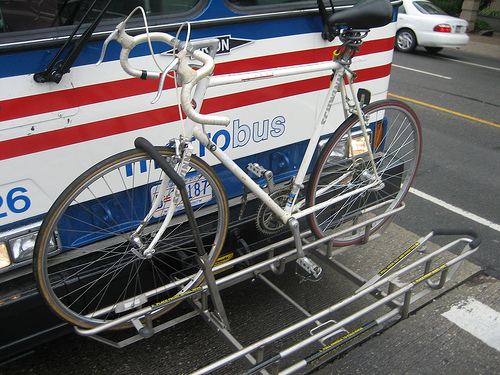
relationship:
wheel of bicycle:
[53, 131, 217, 310] [39, 54, 415, 290]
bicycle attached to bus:
[39, 54, 415, 290] [3, 2, 413, 280]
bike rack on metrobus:
[118, 234, 469, 374] [3, 2, 413, 280]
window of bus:
[6, 4, 187, 24] [3, 2, 413, 280]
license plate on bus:
[131, 176, 205, 207] [2, 43, 396, 194]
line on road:
[393, 60, 463, 89] [435, 130, 492, 181]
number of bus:
[1, 185, 40, 215] [3, 2, 413, 280]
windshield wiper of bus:
[37, 12, 106, 88] [3, 2, 413, 280]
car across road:
[396, 1, 479, 59] [435, 130, 492, 181]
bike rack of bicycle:
[118, 234, 469, 374] [39, 54, 415, 290]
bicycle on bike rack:
[39, 54, 415, 290] [118, 234, 469, 374]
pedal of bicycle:
[294, 252, 331, 279] [39, 54, 415, 290]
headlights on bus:
[2, 231, 53, 265] [3, 2, 413, 280]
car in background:
[396, 1, 479, 59] [395, 4, 496, 271]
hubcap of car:
[398, 32, 412, 50] [396, 1, 479, 59]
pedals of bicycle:
[242, 155, 322, 277] [39, 54, 415, 290]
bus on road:
[3, 2, 413, 280] [435, 130, 492, 181]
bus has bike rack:
[3, 2, 413, 280] [118, 234, 469, 374]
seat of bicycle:
[320, 1, 399, 33] [39, 54, 415, 290]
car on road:
[396, 1, 479, 59] [435, 130, 492, 181]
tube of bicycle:
[220, 144, 292, 203] [39, 54, 415, 290]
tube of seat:
[220, 144, 292, 203] [320, 1, 399, 33]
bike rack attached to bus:
[118, 234, 469, 374] [3, 2, 413, 280]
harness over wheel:
[139, 133, 231, 321] [53, 131, 217, 310]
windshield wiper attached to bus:
[37, 12, 106, 88] [3, 2, 413, 280]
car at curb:
[396, 1, 479, 59] [462, 35, 499, 54]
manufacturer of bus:
[159, 31, 244, 72] [3, 2, 413, 280]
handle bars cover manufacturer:
[90, 19, 239, 127] [159, 31, 244, 72]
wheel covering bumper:
[53, 131, 217, 310] [3, 283, 51, 357]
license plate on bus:
[131, 176, 205, 207] [3, 2, 413, 280]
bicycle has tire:
[39, 54, 415, 290] [305, 93, 425, 248]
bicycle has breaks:
[39, 54, 415, 290] [95, 24, 186, 115]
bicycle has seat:
[39, 54, 415, 290] [320, 1, 399, 33]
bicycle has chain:
[39, 54, 415, 290] [321, 29, 379, 62]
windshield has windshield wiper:
[2, 2, 305, 40] [37, 12, 106, 88]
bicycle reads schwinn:
[39, 54, 415, 290] [319, 72, 345, 126]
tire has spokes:
[305, 93, 425, 248] [387, 133, 412, 170]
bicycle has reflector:
[39, 54, 415, 290] [356, 86, 378, 105]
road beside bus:
[435, 130, 492, 181] [3, 2, 413, 280]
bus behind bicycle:
[3, 2, 413, 280] [39, 54, 415, 290]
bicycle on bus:
[39, 54, 415, 290] [3, 2, 413, 280]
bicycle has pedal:
[39, 54, 415, 290] [294, 252, 331, 279]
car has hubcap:
[396, 1, 479, 59] [398, 32, 412, 50]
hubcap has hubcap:
[398, 32, 412, 50] [398, 32, 412, 50]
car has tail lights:
[396, 1, 479, 59] [430, 21, 469, 36]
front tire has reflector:
[29, 141, 236, 337] [109, 293, 152, 316]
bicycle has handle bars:
[39, 54, 415, 290] [90, 19, 239, 127]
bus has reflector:
[3, 2, 413, 280] [372, 122, 391, 153]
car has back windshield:
[396, 1, 479, 59] [412, 1, 450, 17]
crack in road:
[423, 157, 454, 183] [435, 130, 492, 181]